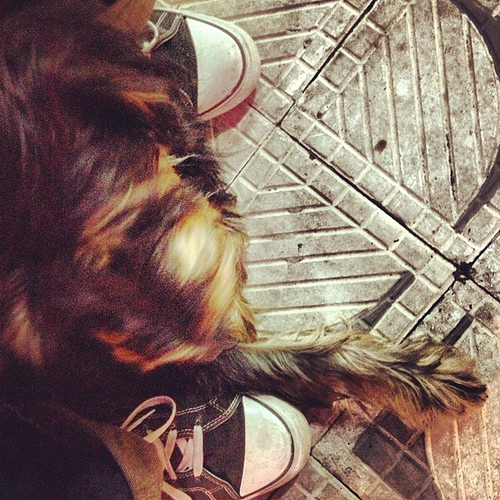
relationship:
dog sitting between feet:
[0, 0, 486, 430] [123, 5, 293, 498]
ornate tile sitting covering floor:
[262, 125, 463, 316] [145, 1, 497, 498]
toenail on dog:
[464, 378, 480, 396] [4, 25, 499, 477]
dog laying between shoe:
[0, 0, 486, 430] [89, 350, 324, 497]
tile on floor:
[279, 3, 499, 268] [145, 1, 497, 498]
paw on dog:
[246, 327, 487, 427] [0, 0, 486, 430]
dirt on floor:
[262, 147, 403, 255] [145, 1, 497, 498]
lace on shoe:
[132, 12, 191, 71] [131, 7, 286, 133]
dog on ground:
[0, 0, 486, 430] [215, 48, 447, 496]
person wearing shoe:
[26, 50, 250, 312] [102, 380, 357, 487]